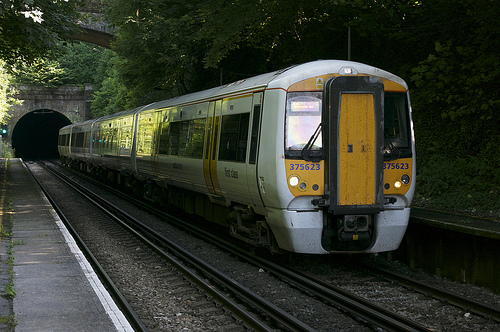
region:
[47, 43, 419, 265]
Train coming out a tunnel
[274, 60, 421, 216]
Front of train is yellow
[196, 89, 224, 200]
Door of train is yellow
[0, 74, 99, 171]
Tunnel behind the train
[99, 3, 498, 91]
Vegetation on left of train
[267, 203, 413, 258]
Bumper of train is white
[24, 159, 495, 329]
Two rails for trains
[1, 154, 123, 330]
Side walk has cracks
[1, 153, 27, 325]
Grass is coming from concrete cracks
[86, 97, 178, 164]
Sun shining on left windows of train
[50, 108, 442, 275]
the train is long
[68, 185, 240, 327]
train track are gray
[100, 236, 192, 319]
there are stones on train tracks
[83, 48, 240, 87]
the trees are green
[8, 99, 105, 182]
the tunnel is black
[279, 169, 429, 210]
the headlights are on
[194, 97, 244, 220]
the doors are close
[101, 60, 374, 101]
the roof is white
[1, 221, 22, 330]
the grass is green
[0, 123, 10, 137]
the traffic light is green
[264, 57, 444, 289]
the train headlights are on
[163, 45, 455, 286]
the train is white and yellow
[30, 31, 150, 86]
the plants are green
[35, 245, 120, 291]
the railway lines are white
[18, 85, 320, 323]
it is in a railway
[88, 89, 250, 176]
reflection is cast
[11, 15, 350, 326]
it is sunny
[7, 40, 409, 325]
it is an outdoor scene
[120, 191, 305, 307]
the railway is made of metal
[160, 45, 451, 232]
train is seen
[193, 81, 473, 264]
train is yellow and white in color.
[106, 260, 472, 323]
Two tracks are seen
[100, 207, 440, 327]
tracks run parallel to each other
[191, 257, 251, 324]
tracks are brown in color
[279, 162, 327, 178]
375623 number written on train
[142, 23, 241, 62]
trees are green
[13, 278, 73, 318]
platform is grey in color.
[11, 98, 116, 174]
tunnel is seen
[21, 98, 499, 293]
daytime picture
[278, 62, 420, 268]
the front of the train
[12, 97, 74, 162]
the enterance to a tunnel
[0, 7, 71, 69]
green leaves hanging from a tree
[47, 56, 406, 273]
a long train on the track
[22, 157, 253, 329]
the empty train track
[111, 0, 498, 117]
a line of trees by the train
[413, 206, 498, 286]
a small path by the train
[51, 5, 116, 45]
a railing above the train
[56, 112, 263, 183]
the windows on the side of the train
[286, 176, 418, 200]
the lights of the train